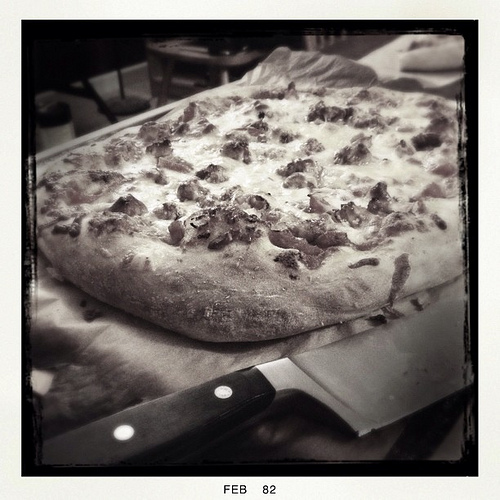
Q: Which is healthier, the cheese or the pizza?
A: The cheese is healthier than the pizza.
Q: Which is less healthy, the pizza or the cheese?
A: The pizza is less healthy than the cheese.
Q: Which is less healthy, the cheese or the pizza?
A: The pizza is less healthy than the cheese.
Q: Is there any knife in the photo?
A: Yes, there is a knife.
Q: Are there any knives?
A: Yes, there is a knife.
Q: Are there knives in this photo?
A: Yes, there is a knife.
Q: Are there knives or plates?
A: Yes, there is a knife.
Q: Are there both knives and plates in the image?
A: No, there is a knife but no plates.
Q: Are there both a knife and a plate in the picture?
A: No, there is a knife but no plates.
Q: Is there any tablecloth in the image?
A: No, there are no tablecloths.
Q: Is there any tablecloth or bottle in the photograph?
A: No, there are no tablecloths or bottles.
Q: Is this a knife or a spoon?
A: This is a knife.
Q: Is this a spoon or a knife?
A: This is a knife.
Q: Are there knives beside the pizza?
A: Yes, there is a knife beside the pizza.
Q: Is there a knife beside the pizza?
A: Yes, there is a knife beside the pizza.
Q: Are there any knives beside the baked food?
A: Yes, there is a knife beside the pizza.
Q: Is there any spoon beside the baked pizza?
A: No, there is a knife beside the pizza.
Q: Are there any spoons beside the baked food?
A: No, there is a knife beside the pizza.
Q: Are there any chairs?
A: Yes, there is a chair.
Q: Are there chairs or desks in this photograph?
A: Yes, there is a chair.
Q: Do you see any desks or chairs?
A: Yes, there is a chair.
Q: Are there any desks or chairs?
A: Yes, there is a chair.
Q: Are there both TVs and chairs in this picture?
A: No, there is a chair but no televisions.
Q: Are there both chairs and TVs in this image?
A: No, there is a chair but no televisions.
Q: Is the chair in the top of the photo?
A: Yes, the chair is in the top of the image.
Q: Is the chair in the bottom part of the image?
A: No, the chair is in the top of the image.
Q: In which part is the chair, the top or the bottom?
A: The chair is in the top of the image.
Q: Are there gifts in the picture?
A: No, there are no gifts.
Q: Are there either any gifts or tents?
A: No, there are no gifts or tents.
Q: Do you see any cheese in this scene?
A: Yes, there is cheese.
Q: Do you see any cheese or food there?
A: Yes, there is cheese.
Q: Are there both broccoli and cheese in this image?
A: No, there is cheese but no broccoli.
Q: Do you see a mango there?
A: No, there are no mangoes.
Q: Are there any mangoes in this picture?
A: No, there are no mangoes.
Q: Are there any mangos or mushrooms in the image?
A: No, there are no mangos or mushrooms.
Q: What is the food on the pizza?
A: The food is cheese.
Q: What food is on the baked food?
A: The food is cheese.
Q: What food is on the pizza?
A: The food is cheese.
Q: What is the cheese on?
A: The cheese is on the pizza.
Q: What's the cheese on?
A: The cheese is on the pizza.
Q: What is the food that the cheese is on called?
A: The food is a pizza.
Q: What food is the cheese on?
A: The cheese is on the pizza.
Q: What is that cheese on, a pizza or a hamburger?
A: The cheese is on a pizza.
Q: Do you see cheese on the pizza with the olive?
A: Yes, there is cheese on the pizza.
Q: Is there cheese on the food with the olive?
A: Yes, there is cheese on the pizza.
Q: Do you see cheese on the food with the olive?
A: Yes, there is cheese on the pizza.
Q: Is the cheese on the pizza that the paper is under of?
A: Yes, the cheese is on the pizza.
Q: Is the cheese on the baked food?
A: Yes, the cheese is on the pizza.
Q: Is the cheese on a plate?
A: No, the cheese is on the pizza.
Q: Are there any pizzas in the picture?
A: Yes, there is a pizza.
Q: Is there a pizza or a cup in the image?
A: Yes, there is a pizza.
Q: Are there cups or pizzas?
A: Yes, there is a pizza.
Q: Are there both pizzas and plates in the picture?
A: No, there is a pizza but no plates.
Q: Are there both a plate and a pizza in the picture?
A: No, there is a pizza but no plates.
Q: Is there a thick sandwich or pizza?
A: Yes, there is a thick pizza.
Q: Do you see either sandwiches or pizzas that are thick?
A: Yes, the pizza is thick.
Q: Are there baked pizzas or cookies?
A: Yes, there is a baked pizza.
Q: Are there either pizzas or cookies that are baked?
A: Yes, the pizza is baked.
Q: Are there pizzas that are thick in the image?
A: Yes, there is a thick pizza.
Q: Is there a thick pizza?
A: Yes, there is a thick pizza.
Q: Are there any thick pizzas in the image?
A: Yes, there is a thick pizza.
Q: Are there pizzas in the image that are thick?
A: Yes, there is a pizza that is thick.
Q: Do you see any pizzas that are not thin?
A: Yes, there is a thick pizza.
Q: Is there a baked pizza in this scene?
A: Yes, there is a baked pizza.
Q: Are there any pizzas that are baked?
A: Yes, there is a pizza that is baked.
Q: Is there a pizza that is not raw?
A: Yes, there is a baked pizza.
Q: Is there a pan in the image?
A: No, there are no pans.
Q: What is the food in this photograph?
A: The food is a pizza.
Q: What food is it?
A: The food is a pizza.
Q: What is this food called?
A: This is a pizza.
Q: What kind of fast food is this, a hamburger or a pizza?
A: This is a pizza.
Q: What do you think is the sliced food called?
A: The food is a pizza.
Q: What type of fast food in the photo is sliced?
A: The fast food is a pizza.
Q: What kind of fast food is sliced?
A: The fast food is a pizza.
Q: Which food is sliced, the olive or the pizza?
A: The pizza is sliced.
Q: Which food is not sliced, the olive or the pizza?
A: The olive is not sliced.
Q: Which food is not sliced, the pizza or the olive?
A: The olive is not sliced.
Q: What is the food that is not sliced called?
A: The food is an olive.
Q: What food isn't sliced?
A: The food is an olive.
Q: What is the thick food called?
A: The food is a pizza.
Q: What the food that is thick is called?
A: The food is a pizza.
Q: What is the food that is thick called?
A: The food is a pizza.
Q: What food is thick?
A: The food is a pizza.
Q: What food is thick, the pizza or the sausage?
A: The pizza is thick.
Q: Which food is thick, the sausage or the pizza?
A: The pizza is thick.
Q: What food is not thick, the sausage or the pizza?
A: The sausage is not thick.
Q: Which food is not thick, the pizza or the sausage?
A: The sausage is not thick.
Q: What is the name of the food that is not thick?
A: The food is a sausage.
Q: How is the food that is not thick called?
A: The food is a sausage.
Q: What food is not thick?
A: The food is a sausage.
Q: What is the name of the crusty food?
A: The food is a pizza.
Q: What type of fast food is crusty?
A: The fast food is a pizza.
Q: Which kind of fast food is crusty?
A: The fast food is a pizza.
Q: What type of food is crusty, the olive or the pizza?
A: The pizza is crusty.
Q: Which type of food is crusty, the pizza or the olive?
A: The pizza is crusty.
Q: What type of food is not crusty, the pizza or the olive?
A: The olive is not crusty.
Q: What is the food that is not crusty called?
A: The food is an olive.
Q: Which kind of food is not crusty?
A: The food is an olive.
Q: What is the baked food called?
A: The food is a pizza.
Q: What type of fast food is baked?
A: The fast food is a pizza.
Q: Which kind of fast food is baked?
A: The fast food is a pizza.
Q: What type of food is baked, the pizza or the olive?
A: The pizza is baked.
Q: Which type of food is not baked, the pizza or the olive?
A: The olive is not baked.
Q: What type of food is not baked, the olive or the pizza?
A: The olive is not baked.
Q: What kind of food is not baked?
A: The food is an olive.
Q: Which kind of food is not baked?
A: The food is an olive.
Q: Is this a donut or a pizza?
A: This is a pizza.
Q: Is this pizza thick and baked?
A: Yes, the pizza is thick and baked.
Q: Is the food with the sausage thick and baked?
A: Yes, the pizza is thick and baked.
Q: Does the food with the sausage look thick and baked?
A: Yes, the pizza is thick and baked.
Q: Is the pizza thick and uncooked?
A: No, the pizza is thick but baked.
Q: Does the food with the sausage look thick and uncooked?
A: No, the pizza is thick but baked.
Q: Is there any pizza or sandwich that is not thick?
A: No, there is a pizza but it is thick.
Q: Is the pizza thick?
A: Yes, the pizza is thick.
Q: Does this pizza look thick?
A: Yes, the pizza is thick.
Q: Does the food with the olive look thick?
A: Yes, the pizza is thick.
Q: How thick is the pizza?
A: The pizza is thick.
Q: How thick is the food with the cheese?
A: The pizza is thick.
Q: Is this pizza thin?
A: No, the pizza is thick.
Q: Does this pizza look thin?
A: No, the pizza is thick.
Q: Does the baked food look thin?
A: No, the pizza is thick.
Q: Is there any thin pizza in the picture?
A: No, there is a pizza but it is thick.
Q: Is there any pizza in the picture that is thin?
A: No, there is a pizza but it is thick.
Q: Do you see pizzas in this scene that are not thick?
A: No, there is a pizza but it is thick.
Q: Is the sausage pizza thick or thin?
A: The pizza is thick.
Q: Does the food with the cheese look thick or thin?
A: The pizza is thick.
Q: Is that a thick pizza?
A: Yes, that is a thick pizza.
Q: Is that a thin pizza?
A: No, that is a thick pizza.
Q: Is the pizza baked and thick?
A: Yes, the pizza is baked and thick.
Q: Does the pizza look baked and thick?
A: Yes, the pizza is baked and thick.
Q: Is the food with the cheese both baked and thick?
A: Yes, the pizza is baked and thick.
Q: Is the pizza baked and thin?
A: No, the pizza is baked but thick.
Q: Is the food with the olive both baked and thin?
A: No, the pizza is baked but thick.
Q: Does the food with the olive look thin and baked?
A: No, the pizza is baked but thick.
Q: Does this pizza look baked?
A: Yes, the pizza is baked.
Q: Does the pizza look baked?
A: Yes, the pizza is baked.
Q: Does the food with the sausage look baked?
A: Yes, the pizza is baked.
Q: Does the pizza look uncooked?
A: No, the pizza is baked.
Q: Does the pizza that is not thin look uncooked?
A: No, the pizza is baked.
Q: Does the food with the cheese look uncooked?
A: No, the pizza is baked.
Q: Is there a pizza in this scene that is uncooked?
A: No, there is a pizza but it is baked.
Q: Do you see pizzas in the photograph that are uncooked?
A: No, there is a pizza but it is baked.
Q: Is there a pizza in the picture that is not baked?
A: No, there is a pizza but it is baked.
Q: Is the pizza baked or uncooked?
A: The pizza is baked.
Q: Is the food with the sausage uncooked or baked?
A: The pizza is baked.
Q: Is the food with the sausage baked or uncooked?
A: The pizza is baked.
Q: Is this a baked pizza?
A: Yes, this is a baked pizza.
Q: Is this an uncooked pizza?
A: No, this is a baked pizza.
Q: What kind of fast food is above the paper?
A: The food is a pizza.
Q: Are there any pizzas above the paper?
A: Yes, there is a pizza above the paper.